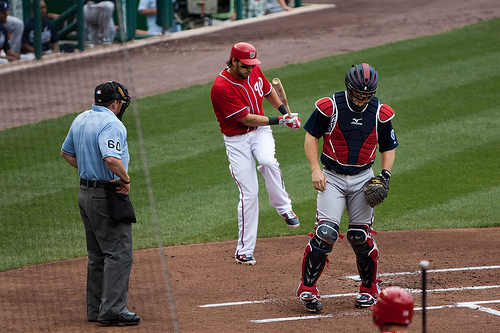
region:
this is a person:
[31, 78, 176, 332]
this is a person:
[186, 43, 298, 274]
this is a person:
[260, 32, 425, 327]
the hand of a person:
[360, 112, 408, 240]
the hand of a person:
[256, 75, 316, 144]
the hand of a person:
[97, 103, 138, 196]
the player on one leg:
[205, 37, 313, 268]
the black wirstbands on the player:
[265, 100, 288, 130]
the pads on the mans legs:
[300, 220, 378, 295]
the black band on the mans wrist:
[120, 175, 134, 186]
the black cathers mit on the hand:
[362, 172, 391, 207]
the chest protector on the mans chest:
[314, 84, 395, 171]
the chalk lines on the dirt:
[449, 255, 499, 330]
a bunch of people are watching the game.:
[0, 0, 334, 40]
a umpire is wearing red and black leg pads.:
[299, 213, 343, 292]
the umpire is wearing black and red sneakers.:
[297, 287, 326, 317]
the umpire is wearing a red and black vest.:
[331, 122, 372, 153]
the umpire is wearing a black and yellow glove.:
[360, 165, 395, 207]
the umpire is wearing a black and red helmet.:
[337, 60, 386, 108]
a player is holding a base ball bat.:
[266, 72, 300, 129]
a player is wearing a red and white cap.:
[226, 41, 264, 71]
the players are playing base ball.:
[48, 18, 435, 331]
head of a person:
[337, 43, 383, 110]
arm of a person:
[300, 89, 333, 187]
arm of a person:
[371, 113, 408, 188]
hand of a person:
[312, 175, 329, 196]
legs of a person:
[292, 193, 399, 308]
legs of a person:
[199, 137, 307, 269]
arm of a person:
[220, 78, 285, 133]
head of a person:
[222, 38, 266, 74]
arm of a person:
[102, 129, 137, 184]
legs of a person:
[71, 193, 150, 330]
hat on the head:
[215, 39, 260, 63]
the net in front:
[34, 269, 81, 306]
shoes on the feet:
[94, 302, 136, 326]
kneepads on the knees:
[307, 215, 335, 246]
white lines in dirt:
[202, 300, 290, 321]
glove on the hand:
[362, 175, 392, 211]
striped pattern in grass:
[420, 70, 481, 191]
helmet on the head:
[342, 59, 378, 101]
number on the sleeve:
[100, 133, 127, 154]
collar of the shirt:
[92, 106, 112, 115]